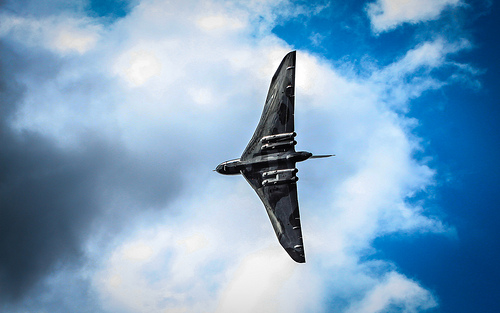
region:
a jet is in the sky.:
[175, 27, 330, 291]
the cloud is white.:
[46, 36, 385, 286]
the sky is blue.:
[274, 30, 498, 303]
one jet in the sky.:
[169, 39, 371, 263]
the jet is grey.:
[198, 36, 345, 261]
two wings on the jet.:
[211, 29, 345, 279]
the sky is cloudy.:
[50, 2, 494, 309]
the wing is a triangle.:
[183, 24, 340, 302]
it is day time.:
[40, 20, 480, 302]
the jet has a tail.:
[180, 42, 354, 269]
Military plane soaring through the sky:
[209, 46, 331, 269]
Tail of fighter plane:
[308, 146, 337, 163]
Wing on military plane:
[248, 187, 318, 266]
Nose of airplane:
[211, 159, 241, 176]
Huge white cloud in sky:
[64, 2, 404, 311]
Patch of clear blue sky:
[426, 107, 498, 291]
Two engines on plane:
[254, 126, 299, 148]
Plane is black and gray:
[205, 44, 340, 268]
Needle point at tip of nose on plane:
[211, 167, 214, 172]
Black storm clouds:
[4, 115, 166, 272]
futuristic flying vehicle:
[159, 5, 388, 304]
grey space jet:
[207, 22, 370, 302]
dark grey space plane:
[181, 22, 367, 295]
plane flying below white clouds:
[117, 20, 412, 303]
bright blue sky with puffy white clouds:
[323, 10, 483, 288]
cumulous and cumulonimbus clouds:
[9, 20, 150, 311]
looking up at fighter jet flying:
[21, 9, 473, 299]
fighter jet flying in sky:
[85, 13, 417, 279]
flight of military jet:
[69, 10, 459, 291]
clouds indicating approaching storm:
[2, 13, 203, 288]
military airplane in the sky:
[213, 43, 330, 285]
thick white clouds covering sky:
[75, 88, 189, 277]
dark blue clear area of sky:
[456, 197, 486, 284]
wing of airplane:
[251, 41, 312, 156]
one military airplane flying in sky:
[180, 28, 344, 270]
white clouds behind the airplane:
[123, 34, 232, 153]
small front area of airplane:
[210, 148, 254, 178]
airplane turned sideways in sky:
[187, 30, 342, 278]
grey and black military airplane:
[190, 42, 335, 274]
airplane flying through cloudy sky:
[180, 27, 380, 291]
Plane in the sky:
[205, 42, 337, 272]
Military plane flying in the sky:
[196, 44, 343, 270]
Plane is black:
[201, 38, 343, 270]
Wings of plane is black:
[239, 37, 308, 272]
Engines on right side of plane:
[252, 125, 299, 155]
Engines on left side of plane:
[254, 163, 302, 187]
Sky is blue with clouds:
[0, 0, 496, 310]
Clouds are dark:
[8, 133, 98, 288]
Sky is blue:
[438, 110, 498, 310]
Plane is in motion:
[204, 39, 346, 283]